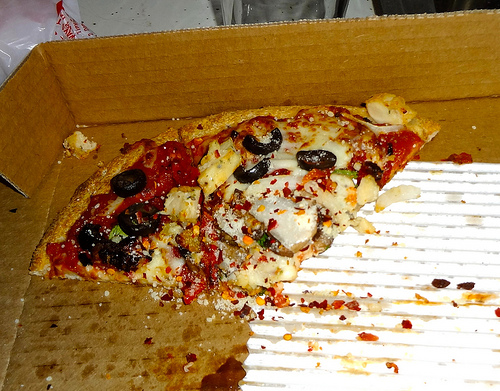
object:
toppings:
[45, 116, 420, 284]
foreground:
[0, 94, 499, 389]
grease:
[149, 344, 193, 391]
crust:
[175, 103, 439, 140]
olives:
[362, 161, 383, 180]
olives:
[99, 237, 154, 271]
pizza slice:
[181, 92, 438, 290]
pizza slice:
[31, 128, 226, 287]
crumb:
[64, 131, 97, 158]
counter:
[59, 0, 216, 37]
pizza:
[27, 95, 439, 303]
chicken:
[197, 137, 240, 195]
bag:
[0, 0, 94, 87]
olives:
[110, 169, 147, 198]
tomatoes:
[114, 139, 201, 212]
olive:
[296, 150, 337, 170]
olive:
[233, 161, 268, 183]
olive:
[242, 127, 283, 154]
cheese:
[216, 120, 356, 251]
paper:
[237, 160, 499, 390]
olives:
[118, 206, 158, 236]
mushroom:
[365, 93, 417, 125]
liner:
[301, 267, 499, 281]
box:
[0, 9, 499, 391]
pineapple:
[197, 151, 242, 196]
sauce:
[379, 130, 423, 184]